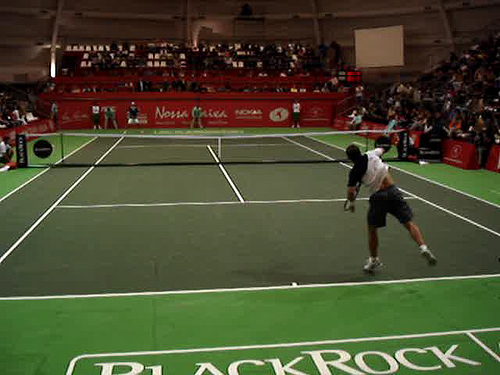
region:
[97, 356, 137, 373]
white letter on ground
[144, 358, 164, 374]
white letter on ground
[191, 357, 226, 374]
white letter on ground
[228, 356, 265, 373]
white letter on ground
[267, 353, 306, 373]
white letter on ground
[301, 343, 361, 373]
white letter on ground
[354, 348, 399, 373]
white letter on ground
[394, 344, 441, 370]
white letter on ground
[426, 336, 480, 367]
white letter on ground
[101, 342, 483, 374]
white letter on ground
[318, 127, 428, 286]
this is a tennis player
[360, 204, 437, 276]
these are the legs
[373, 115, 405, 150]
he is swinging the racket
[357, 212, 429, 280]
the legs are apart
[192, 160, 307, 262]
this is the pitch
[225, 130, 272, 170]
this is the net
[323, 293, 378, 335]
the pitch is green in collor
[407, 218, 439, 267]
the leg is raised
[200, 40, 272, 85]
these are the spectators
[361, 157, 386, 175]
this is the t shirt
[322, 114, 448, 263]
man wearing black shorts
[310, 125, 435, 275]
man holding tennis racket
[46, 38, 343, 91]
people sitting in stands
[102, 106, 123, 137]
man wearing green shirt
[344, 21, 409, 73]
white projection screen on wall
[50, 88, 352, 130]
red sign with white words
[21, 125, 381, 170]
white net on courts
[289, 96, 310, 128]
man wearing white shirt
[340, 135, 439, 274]
A man swinging a tennis racket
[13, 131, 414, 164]
A net bisecting a tennis court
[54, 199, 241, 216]
White line painted on a tennis court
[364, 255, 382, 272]
White shoes on a green court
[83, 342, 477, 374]
White lettering on a green tennis court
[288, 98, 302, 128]
Man standing against a red backstop.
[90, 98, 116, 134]
People standing against the red backstop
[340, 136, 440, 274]
An athlete swinging a racket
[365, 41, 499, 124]
People in the stands watching tennis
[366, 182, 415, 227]
Player wearing black shorts